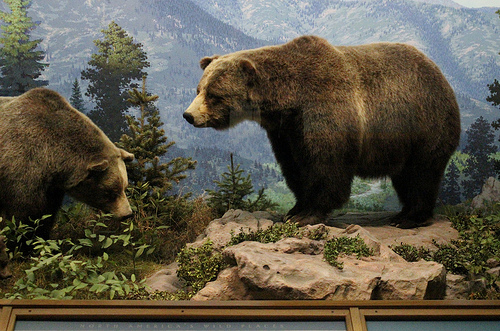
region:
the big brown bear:
[185, 32, 454, 224]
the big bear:
[182, 36, 464, 235]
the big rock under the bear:
[152, 197, 485, 303]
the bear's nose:
[176, 108, 193, 125]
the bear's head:
[178, 50, 263, 135]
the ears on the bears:
[195, 52, 255, 73]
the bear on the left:
[3, 85, 137, 222]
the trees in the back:
[7, 1, 189, 249]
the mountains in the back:
[60, 2, 347, 194]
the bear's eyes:
[191, 85, 215, 100]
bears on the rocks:
[4, 28, 476, 253]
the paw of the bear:
[281, 202, 437, 233]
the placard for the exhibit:
[15, 297, 497, 329]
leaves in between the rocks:
[178, 225, 359, 287]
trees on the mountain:
[147, 1, 227, 46]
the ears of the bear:
[87, 136, 135, 178]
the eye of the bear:
[204, 88, 224, 101]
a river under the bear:
[355, 180, 382, 200]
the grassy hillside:
[331, 12, 346, 35]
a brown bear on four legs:
[177, 30, 452, 221]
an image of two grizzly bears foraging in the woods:
[0, 0, 499, 300]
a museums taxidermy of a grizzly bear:
[183, 35, 463, 227]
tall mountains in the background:
[29, 0, 499, 39]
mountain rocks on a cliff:
[145, 224, 499, 301]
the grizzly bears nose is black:
[182, 109, 196, 125]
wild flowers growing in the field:
[1, 219, 154, 299]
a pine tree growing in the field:
[117, 71, 194, 235]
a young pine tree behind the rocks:
[209, 151, 273, 215]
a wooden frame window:
[1, 298, 498, 329]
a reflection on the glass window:
[199, 56, 279, 174]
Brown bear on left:
[4, 3, 141, 248]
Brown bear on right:
[186, 31, 476, 215]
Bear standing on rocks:
[159, 23, 478, 299]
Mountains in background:
[6, 5, 499, 198]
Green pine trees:
[3, 6, 196, 204]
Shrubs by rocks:
[5, 207, 190, 302]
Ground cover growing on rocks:
[137, 208, 499, 303]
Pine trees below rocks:
[167, 142, 288, 237]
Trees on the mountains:
[18, 12, 497, 187]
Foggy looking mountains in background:
[29, 11, 499, 207]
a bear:
[156, 13, 438, 216]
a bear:
[197, 24, 372, 181]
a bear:
[231, 53, 444, 261]